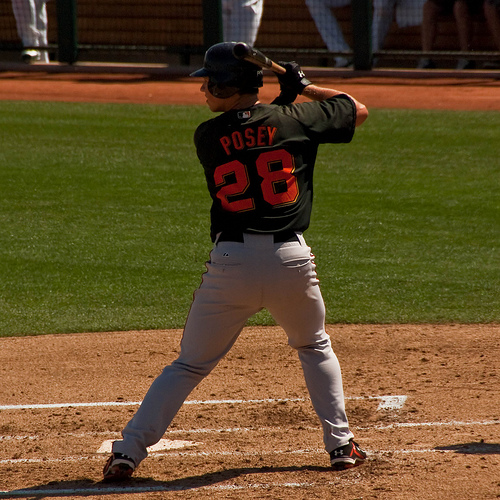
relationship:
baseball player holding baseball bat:
[96, 38, 370, 484] [233, 42, 289, 80]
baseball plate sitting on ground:
[99, 434, 200, 455] [1, 60, 499, 500]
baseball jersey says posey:
[190, 93, 355, 235] [219, 121, 279, 157]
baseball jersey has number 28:
[190, 93, 355, 235] [211, 149, 305, 216]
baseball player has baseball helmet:
[96, 38, 370, 484] [190, 41, 262, 79]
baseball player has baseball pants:
[96, 38, 370, 484] [107, 233, 353, 454]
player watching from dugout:
[12, 1, 52, 66] [1, 2, 499, 71]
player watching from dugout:
[222, 3, 265, 57] [1, 2, 499, 71]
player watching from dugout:
[308, 3, 399, 66] [1, 2, 499, 71]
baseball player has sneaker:
[96, 38, 370, 484] [99, 450, 137, 481]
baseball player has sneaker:
[96, 38, 370, 484] [327, 436, 367, 466]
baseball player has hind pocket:
[96, 38, 370, 484] [279, 252, 312, 280]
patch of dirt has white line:
[1, 312, 499, 499] [1, 394, 409, 417]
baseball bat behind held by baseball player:
[233, 42, 289, 80] [96, 38, 370, 484]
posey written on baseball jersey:
[219, 121, 279, 157] [190, 93, 355, 235]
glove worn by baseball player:
[281, 61, 311, 92] [96, 38, 370, 484]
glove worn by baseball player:
[276, 76, 299, 104] [96, 38, 370, 484]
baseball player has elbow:
[96, 38, 370, 484] [351, 98, 371, 128]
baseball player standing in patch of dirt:
[96, 38, 370, 484] [1, 312, 499, 499]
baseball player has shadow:
[96, 38, 370, 484] [14, 454, 348, 499]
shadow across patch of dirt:
[14, 454, 348, 499] [1, 312, 499, 499]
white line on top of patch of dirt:
[1, 394, 409, 417] [1, 312, 499, 499]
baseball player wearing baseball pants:
[96, 38, 370, 484] [107, 233, 353, 454]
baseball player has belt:
[96, 38, 370, 484] [212, 230, 304, 246]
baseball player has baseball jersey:
[96, 38, 370, 484] [190, 93, 355, 235]